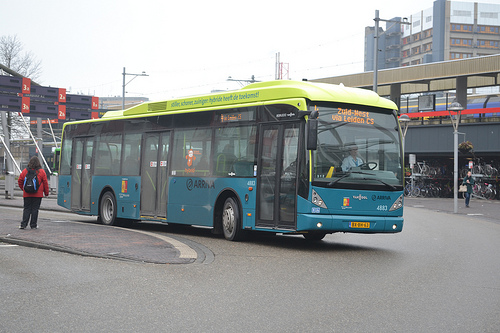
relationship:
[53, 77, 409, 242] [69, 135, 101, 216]
bus has door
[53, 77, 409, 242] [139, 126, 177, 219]
bus has door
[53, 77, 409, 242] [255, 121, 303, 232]
bus has door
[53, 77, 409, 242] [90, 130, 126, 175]
bus has window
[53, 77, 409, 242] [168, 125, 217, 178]
bus has window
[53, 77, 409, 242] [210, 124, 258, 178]
bus has window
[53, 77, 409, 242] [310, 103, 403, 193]
bus has windshield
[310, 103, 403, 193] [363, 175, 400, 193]
windshield has wiper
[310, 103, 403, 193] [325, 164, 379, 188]
windshield has wiper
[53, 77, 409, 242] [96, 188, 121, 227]
bus has tire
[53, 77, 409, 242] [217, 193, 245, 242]
bus has tire